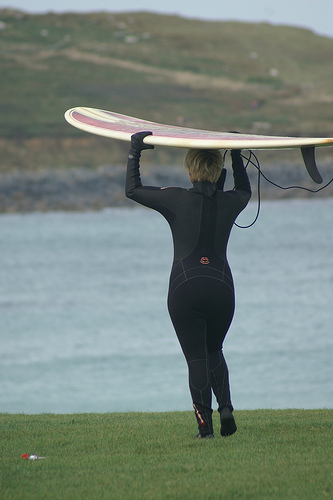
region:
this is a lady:
[118, 128, 273, 446]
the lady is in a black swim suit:
[125, 135, 264, 445]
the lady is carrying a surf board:
[45, 96, 331, 182]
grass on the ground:
[18, 413, 196, 498]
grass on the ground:
[200, 445, 280, 494]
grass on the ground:
[288, 406, 331, 476]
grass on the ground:
[0, 415, 58, 461]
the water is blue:
[0, 190, 326, 408]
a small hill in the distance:
[2, 2, 328, 187]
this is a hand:
[120, 120, 179, 218]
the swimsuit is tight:
[157, 206, 256, 412]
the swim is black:
[128, 198, 247, 408]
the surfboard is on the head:
[69, 105, 326, 155]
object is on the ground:
[14, 441, 49, 470]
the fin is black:
[295, 148, 326, 179]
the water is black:
[39, 339, 171, 400]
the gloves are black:
[121, 126, 159, 152]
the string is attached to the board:
[241, 159, 308, 215]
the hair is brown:
[185, 152, 228, 181]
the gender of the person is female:
[104, 126, 270, 448]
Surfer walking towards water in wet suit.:
[63, 107, 331, 438]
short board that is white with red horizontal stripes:
[63, 105, 330, 148]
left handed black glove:
[129, 130, 154, 157]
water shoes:
[218, 407, 236, 437]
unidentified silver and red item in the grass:
[20, 453, 46, 461]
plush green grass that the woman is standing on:
[0, 408, 332, 499]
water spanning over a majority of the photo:
[0, 198, 332, 412]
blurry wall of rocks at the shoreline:
[0, 160, 332, 212]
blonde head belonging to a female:
[183, 148, 223, 181]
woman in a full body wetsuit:
[123, 130, 251, 439]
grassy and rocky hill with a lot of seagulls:
[0, 7, 332, 171]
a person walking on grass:
[110, 116, 280, 462]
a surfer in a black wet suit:
[113, 120, 272, 447]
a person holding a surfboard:
[59, 98, 332, 446]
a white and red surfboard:
[60, 97, 331, 189]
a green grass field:
[2, 405, 331, 498]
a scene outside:
[0, 3, 331, 488]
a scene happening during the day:
[4, 10, 332, 499]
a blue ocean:
[0, 189, 331, 409]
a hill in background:
[1, 3, 331, 221]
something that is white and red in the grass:
[12, 444, 53, 465]